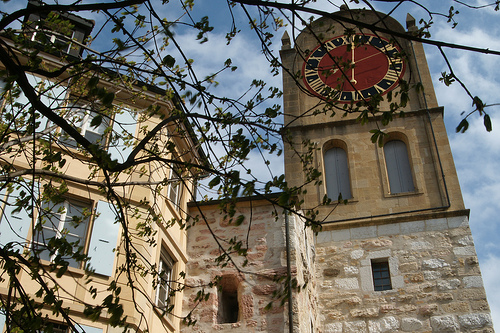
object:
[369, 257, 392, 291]
small window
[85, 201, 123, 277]
shutter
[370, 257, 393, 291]
window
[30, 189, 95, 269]
window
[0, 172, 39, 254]
shutter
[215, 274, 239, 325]
window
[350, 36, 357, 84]
hand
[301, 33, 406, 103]
clock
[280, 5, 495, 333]
clock tower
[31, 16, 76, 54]
window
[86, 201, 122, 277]
window shutter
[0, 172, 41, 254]
window shutter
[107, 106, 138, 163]
window shutter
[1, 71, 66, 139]
window shutter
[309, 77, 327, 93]
roman numerals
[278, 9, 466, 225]
wall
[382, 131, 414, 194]
arched window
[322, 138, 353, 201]
arched window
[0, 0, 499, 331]
sky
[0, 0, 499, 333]
building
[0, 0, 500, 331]
cloud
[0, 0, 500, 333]
branches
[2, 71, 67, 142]
shutter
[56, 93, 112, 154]
window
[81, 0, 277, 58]
streak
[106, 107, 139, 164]
shutter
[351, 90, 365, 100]
roman numeral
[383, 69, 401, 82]
roman numeral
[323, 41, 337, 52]
roman numeral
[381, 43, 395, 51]
roman numeral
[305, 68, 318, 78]
roman numeral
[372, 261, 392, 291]
frame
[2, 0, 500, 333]
outside